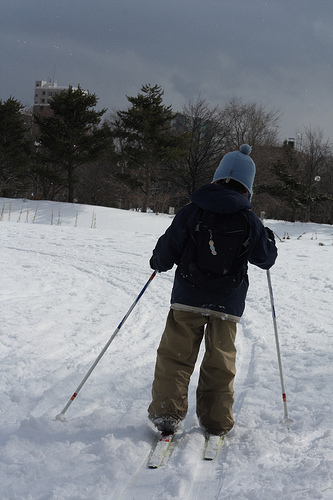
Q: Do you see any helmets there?
A: No, there are no helmets.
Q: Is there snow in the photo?
A: Yes, there is snow.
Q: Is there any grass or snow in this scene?
A: Yes, there is snow.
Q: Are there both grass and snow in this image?
A: No, there is snow but no grass.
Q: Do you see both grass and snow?
A: No, there is snow but no grass.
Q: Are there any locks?
A: No, there are no locks.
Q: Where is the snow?
A: The snow is on the ground.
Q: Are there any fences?
A: Yes, there is a fence.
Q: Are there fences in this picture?
A: Yes, there is a fence.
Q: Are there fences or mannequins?
A: Yes, there is a fence.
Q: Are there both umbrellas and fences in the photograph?
A: No, there is a fence but no umbrellas.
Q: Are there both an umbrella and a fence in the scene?
A: No, there is a fence but no umbrellas.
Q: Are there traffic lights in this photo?
A: No, there are no traffic lights.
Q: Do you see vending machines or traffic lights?
A: No, there are no traffic lights or vending machines.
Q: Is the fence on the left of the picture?
A: Yes, the fence is on the left of the image.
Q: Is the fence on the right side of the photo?
A: No, the fence is on the left of the image.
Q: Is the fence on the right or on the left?
A: The fence is on the left of the image.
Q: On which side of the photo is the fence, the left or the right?
A: The fence is on the left of the image.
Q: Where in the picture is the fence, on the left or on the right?
A: The fence is on the left of the image.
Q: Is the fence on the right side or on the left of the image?
A: The fence is on the left of the image.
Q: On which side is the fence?
A: The fence is on the left of the image.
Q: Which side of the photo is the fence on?
A: The fence is on the left of the image.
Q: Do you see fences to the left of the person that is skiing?
A: Yes, there is a fence to the left of the person.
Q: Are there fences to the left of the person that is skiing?
A: Yes, there is a fence to the left of the person.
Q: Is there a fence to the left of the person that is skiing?
A: Yes, there is a fence to the left of the person.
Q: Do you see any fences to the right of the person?
A: No, the fence is to the left of the person.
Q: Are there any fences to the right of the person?
A: No, the fence is to the left of the person.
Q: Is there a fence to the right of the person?
A: No, the fence is to the left of the person.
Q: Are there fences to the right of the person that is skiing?
A: No, the fence is to the left of the person.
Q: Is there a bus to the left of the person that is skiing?
A: No, there is a fence to the left of the person.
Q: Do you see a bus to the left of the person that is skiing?
A: No, there is a fence to the left of the person.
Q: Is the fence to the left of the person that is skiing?
A: Yes, the fence is to the left of the person.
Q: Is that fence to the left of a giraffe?
A: No, the fence is to the left of the person.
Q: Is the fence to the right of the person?
A: No, the fence is to the left of the person.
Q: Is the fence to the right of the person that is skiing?
A: No, the fence is to the left of the person.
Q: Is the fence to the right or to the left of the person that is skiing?
A: The fence is to the left of the person.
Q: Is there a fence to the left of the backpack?
A: Yes, there is a fence to the left of the backpack.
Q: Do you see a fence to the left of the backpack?
A: Yes, there is a fence to the left of the backpack.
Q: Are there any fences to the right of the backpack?
A: No, the fence is to the left of the backpack.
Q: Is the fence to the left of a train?
A: No, the fence is to the left of the backpack.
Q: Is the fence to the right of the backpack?
A: No, the fence is to the left of the backpack.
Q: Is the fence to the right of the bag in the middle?
A: No, the fence is to the left of the backpack.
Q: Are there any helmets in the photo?
A: No, there are no helmets.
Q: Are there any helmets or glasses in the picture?
A: No, there are no helmets or glasses.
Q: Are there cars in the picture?
A: No, there are no cars.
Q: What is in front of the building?
A: The trees are in front of the building.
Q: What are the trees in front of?
A: The trees are in front of the building.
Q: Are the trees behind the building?
A: No, the trees are in front of the building.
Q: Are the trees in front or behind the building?
A: The trees are in front of the building.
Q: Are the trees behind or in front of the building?
A: The trees are in front of the building.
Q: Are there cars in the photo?
A: No, there are no cars.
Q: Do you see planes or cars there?
A: No, there are no cars or planes.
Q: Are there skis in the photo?
A: Yes, there are skis.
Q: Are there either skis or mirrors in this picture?
A: Yes, there are skis.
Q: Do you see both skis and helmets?
A: No, there are skis but no helmets.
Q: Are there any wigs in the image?
A: No, there are no wigs.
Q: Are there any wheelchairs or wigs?
A: No, there are no wigs or wheelchairs.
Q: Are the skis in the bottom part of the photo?
A: Yes, the skis are in the bottom of the image.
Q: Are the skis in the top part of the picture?
A: No, the skis are in the bottom of the image.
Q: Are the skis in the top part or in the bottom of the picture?
A: The skis are in the bottom of the image.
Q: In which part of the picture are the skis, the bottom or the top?
A: The skis are in the bottom of the image.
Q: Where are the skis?
A: The skis are in the snow.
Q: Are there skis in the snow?
A: Yes, there are skis in the snow.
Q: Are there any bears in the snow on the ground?
A: No, there are skis in the snow.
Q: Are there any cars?
A: No, there are no cars.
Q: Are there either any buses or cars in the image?
A: No, there are no cars or buses.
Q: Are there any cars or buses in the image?
A: No, there are no cars or buses.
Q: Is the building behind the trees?
A: Yes, the building is behind the trees.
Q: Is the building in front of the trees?
A: No, the building is behind the trees.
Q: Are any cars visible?
A: No, there are no cars.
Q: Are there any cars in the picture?
A: No, there are no cars.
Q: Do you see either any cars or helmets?
A: No, there are no cars or helmets.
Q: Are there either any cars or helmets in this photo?
A: No, there are no cars or helmets.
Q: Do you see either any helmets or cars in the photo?
A: No, there are no cars or helmets.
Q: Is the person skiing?
A: Yes, the person is skiing.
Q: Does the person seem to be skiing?
A: Yes, the person is skiing.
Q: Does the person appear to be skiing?
A: Yes, the person is skiing.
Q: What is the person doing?
A: The person is skiing.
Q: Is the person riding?
A: No, the person is skiing.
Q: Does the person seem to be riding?
A: No, the person is skiing.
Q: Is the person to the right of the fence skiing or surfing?
A: The person is skiing.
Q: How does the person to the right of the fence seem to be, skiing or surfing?
A: The person is skiing.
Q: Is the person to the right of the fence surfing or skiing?
A: The person is skiing.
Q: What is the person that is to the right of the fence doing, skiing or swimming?
A: The person is skiing.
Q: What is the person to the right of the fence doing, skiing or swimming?
A: The person is skiing.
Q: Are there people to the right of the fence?
A: Yes, there is a person to the right of the fence.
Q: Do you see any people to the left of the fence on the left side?
A: No, the person is to the right of the fence.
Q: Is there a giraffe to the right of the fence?
A: No, there is a person to the right of the fence.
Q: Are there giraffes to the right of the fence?
A: No, there is a person to the right of the fence.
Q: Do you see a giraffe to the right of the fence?
A: No, there is a person to the right of the fence.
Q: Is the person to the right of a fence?
A: Yes, the person is to the right of a fence.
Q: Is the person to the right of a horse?
A: No, the person is to the right of a fence.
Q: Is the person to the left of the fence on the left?
A: No, the person is to the right of the fence.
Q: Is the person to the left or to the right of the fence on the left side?
A: The person is to the right of the fence.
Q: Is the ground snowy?
A: Yes, the ground is snowy.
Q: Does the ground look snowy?
A: Yes, the ground is snowy.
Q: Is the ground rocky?
A: No, the ground is snowy.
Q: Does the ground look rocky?
A: No, the ground is snowy.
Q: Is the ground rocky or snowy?
A: The ground is snowy.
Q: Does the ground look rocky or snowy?
A: The ground is snowy.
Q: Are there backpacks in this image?
A: Yes, there is a backpack.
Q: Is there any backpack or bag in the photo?
A: Yes, there is a backpack.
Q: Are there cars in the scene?
A: No, there are no cars.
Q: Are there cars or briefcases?
A: No, there are no cars or briefcases.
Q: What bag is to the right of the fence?
A: The bag is a backpack.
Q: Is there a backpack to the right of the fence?
A: Yes, there is a backpack to the right of the fence.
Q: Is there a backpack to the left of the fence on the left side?
A: No, the backpack is to the right of the fence.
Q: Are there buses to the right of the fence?
A: No, there is a backpack to the right of the fence.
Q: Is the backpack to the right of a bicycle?
A: No, the backpack is to the right of the fence.